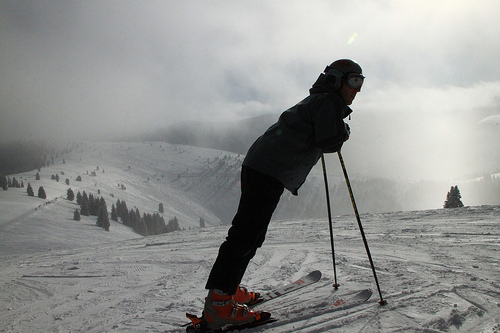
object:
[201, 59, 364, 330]
man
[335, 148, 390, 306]
poles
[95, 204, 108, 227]
trees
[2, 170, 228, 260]
slope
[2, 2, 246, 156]
mist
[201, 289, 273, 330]
boots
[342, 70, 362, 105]
face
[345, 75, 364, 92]
goggles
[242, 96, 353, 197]
coat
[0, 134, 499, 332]
snow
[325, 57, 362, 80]
helmet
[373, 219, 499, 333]
marks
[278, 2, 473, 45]
sunlight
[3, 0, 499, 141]
sky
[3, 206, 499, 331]
ground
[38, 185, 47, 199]
trees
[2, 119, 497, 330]
hill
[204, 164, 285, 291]
pants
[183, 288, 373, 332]
skis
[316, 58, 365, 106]
ahead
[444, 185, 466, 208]
tree